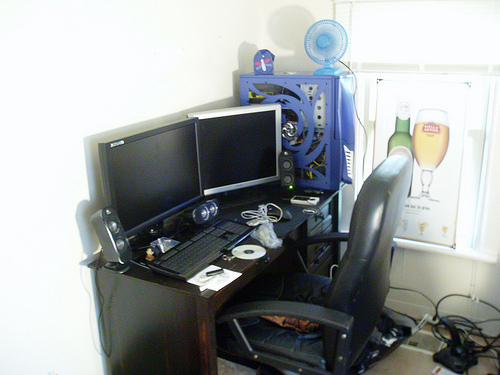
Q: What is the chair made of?
A: Leather.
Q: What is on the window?
A: A poster.